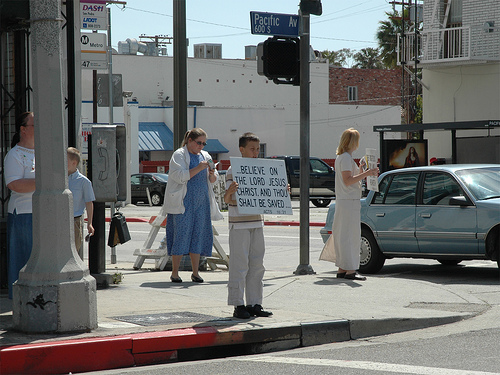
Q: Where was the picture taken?
A: It was taken at the sidewalk.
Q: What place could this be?
A: It is a sidewalk.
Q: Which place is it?
A: It is a sidewalk.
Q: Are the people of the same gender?
A: No, they are both male and female.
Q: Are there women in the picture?
A: Yes, there is a woman.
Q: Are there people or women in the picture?
A: Yes, there is a woman.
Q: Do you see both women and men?
A: No, there is a woman but no men.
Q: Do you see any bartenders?
A: No, there are no bartenders.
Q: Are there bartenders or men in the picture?
A: No, there are no bartenders or men.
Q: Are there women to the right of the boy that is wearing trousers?
A: Yes, there is a woman to the right of the boy.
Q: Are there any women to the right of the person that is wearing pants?
A: Yes, there is a woman to the right of the boy.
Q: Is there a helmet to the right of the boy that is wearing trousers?
A: No, there is a woman to the right of the boy.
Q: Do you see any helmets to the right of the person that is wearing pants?
A: No, there is a woman to the right of the boy.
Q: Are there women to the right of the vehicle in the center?
A: Yes, there is a woman to the right of the truck.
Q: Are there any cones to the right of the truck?
A: No, there is a woman to the right of the truck.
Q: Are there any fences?
A: No, there are no fences.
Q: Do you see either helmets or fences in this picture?
A: No, there are no fences or helmets.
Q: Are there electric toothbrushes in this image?
A: No, there are no electric toothbrushes.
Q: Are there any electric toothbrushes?
A: No, there are no electric toothbrushes.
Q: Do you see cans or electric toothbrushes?
A: No, there are no electric toothbrushes or cans.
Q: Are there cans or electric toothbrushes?
A: No, there are no electric toothbrushes or cans.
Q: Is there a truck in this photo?
A: Yes, there is a truck.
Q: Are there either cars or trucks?
A: Yes, there is a truck.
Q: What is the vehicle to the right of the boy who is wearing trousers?
A: The vehicle is a truck.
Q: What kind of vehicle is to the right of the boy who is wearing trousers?
A: The vehicle is a truck.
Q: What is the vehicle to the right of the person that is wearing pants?
A: The vehicle is a truck.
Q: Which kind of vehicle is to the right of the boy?
A: The vehicle is a truck.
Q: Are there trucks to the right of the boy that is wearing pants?
A: Yes, there is a truck to the right of the boy.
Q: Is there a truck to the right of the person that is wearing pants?
A: Yes, there is a truck to the right of the boy.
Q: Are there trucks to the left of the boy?
A: No, the truck is to the right of the boy.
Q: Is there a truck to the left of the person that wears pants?
A: No, the truck is to the right of the boy.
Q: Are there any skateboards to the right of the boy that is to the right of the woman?
A: No, there is a truck to the right of the boy.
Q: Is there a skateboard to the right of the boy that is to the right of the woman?
A: No, there is a truck to the right of the boy.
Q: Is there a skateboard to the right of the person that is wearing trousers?
A: No, there is a truck to the right of the boy.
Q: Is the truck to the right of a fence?
A: No, the truck is to the right of the boy.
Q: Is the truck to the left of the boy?
A: No, the truck is to the right of the boy.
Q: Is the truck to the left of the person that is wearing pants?
A: No, the truck is to the right of the boy.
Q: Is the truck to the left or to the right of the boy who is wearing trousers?
A: The truck is to the right of the boy.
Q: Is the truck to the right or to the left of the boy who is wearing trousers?
A: The truck is to the right of the boy.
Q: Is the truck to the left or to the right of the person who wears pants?
A: The truck is to the right of the boy.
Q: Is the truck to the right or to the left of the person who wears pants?
A: The truck is to the right of the boy.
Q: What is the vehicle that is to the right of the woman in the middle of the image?
A: The vehicle is a truck.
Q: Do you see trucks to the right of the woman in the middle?
A: Yes, there is a truck to the right of the woman.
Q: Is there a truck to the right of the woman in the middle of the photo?
A: Yes, there is a truck to the right of the woman.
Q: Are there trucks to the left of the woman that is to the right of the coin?
A: No, the truck is to the right of the woman.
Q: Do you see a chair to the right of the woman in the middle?
A: No, there is a truck to the right of the woman.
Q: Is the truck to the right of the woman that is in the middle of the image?
A: Yes, the truck is to the right of the woman.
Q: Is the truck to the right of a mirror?
A: No, the truck is to the right of the woman.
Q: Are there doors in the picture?
A: Yes, there is a door.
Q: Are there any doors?
A: Yes, there is a door.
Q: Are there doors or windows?
A: Yes, there is a door.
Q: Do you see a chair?
A: No, there are no chairs.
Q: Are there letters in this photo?
A: Yes, there are letters.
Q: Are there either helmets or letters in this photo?
A: Yes, there are letters.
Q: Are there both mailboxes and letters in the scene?
A: No, there are letters but no mailboxes.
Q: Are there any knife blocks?
A: No, there are no knife blocks.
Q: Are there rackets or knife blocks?
A: No, there are no knife blocks or rackets.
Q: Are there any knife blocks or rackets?
A: No, there are no knife blocks or rackets.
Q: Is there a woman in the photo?
A: Yes, there is a woman.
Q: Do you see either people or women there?
A: Yes, there is a woman.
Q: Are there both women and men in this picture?
A: No, there is a woman but no men.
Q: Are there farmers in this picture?
A: No, there are no farmers.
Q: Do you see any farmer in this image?
A: No, there are no farmers.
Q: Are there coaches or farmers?
A: No, there are no farmers or coaches.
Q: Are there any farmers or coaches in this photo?
A: No, there are no farmers or coaches.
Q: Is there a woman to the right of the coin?
A: Yes, there is a woman to the right of the coin.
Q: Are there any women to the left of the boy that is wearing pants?
A: Yes, there is a woman to the left of the boy.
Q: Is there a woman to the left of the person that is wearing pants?
A: Yes, there is a woman to the left of the boy.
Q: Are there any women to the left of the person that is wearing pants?
A: Yes, there is a woman to the left of the boy.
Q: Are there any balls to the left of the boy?
A: No, there is a woman to the left of the boy.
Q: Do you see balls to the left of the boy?
A: No, there is a woman to the left of the boy.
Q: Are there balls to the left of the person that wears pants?
A: No, there is a woman to the left of the boy.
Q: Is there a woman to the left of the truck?
A: Yes, there is a woman to the left of the truck.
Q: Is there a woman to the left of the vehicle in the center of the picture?
A: Yes, there is a woman to the left of the truck.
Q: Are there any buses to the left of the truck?
A: No, there is a woman to the left of the truck.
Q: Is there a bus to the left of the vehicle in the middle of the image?
A: No, there is a woman to the left of the truck.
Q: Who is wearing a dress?
A: The woman is wearing a dress.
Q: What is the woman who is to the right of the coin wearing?
A: The woman is wearing a dress.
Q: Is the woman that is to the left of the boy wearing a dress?
A: Yes, the woman is wearing a dress.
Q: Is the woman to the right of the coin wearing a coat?
A: No, the woman is wearing a dress.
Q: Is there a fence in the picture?
A: No, there are no fences.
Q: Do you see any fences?
A: No, there are no fences.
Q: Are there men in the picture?
A: No, there are no men.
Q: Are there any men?
A: No, there are no men.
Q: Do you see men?
A: No, there are no men.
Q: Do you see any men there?
A: No, there are no men.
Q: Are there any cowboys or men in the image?
A: No, there are no men or cowboys.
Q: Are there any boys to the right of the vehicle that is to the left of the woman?
A: No, the boy is to the left of the truck.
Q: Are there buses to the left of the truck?
A: No, there is a boy to the left of the truck.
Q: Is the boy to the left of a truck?
A: Yes, the boy is to the left of a truck.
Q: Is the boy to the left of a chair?
A: No, the boy is to the left of a truck.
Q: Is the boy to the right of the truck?
A: No, the boy is to the left of the truck.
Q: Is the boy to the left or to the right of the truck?
A: The boy is to the left of the truck.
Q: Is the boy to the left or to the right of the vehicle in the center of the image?
A: The boy is to the left of the truck.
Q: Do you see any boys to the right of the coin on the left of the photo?
A: Yes, there is a boy to the right of the coin.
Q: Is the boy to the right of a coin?
A: Yes, the boy is to the right of a coin.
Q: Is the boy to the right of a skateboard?
A: No, the boy is to the right of a coin.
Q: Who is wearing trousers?
A: The boy is wearing trousers.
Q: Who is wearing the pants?
A: The boy is wearing trousers.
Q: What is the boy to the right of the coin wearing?
A: The boy is wearing trousers.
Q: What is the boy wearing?
A: The boy is wearing trousers.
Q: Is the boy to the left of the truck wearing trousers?
A: Yes, the boy is wearing trousers.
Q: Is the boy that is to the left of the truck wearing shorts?
A: No, the boy is wearing trousers.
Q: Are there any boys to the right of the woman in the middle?
A: Yes, there is a boy to the right of the woman.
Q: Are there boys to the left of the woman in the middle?
A: No, the boy is to the right of the woman.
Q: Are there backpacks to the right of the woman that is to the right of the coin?
A: No, there is a boy to the right of the woman.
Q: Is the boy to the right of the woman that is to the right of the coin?
A: Yes, the boy is to the right of the woman.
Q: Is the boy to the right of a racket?
A: No, the boy is to the right of the woman.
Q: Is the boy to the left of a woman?
A: No, the boy is to the right of a woman.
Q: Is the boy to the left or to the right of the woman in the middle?
A: The boy is to the right of the woman.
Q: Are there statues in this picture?
A: No, there are no statues.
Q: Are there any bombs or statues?
A: No, there are no statues or bombs.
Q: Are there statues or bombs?
A: No, there are no statues or bombs.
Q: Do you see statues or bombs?
A: No, there are no statues or bombs.